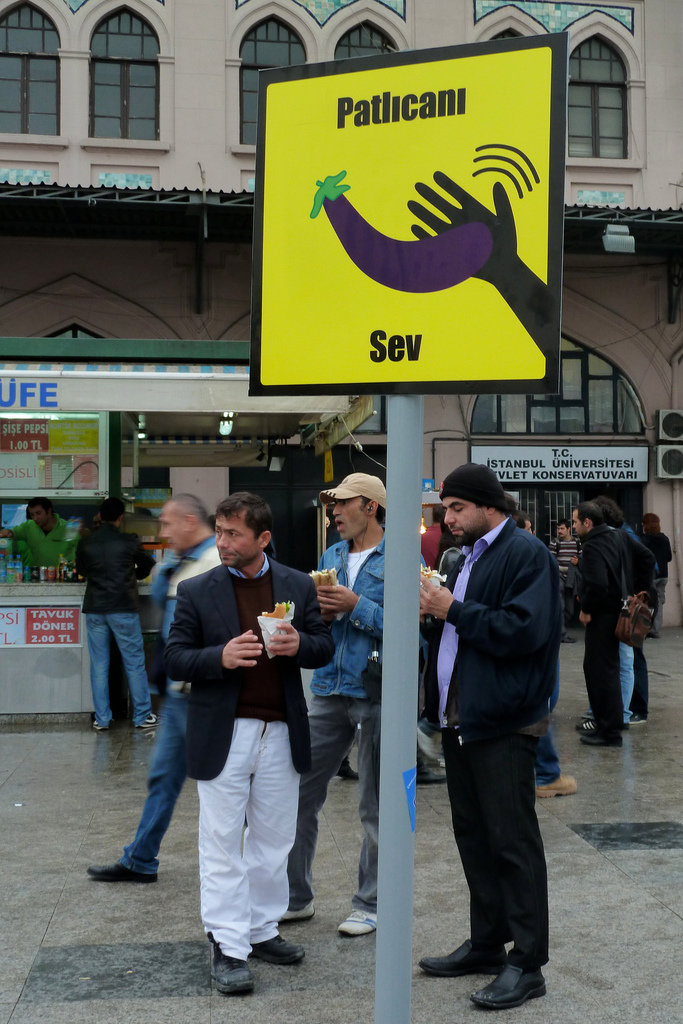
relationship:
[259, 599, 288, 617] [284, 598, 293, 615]
sandwich with lettuce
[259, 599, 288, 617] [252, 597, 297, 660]
sandwich wrapped in paper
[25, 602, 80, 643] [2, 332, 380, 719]
sign on kiosk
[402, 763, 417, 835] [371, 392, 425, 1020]
sign on utility pole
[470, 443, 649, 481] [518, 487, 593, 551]
sign above doorway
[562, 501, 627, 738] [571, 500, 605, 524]
man with hair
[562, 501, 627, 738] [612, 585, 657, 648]
man carries bag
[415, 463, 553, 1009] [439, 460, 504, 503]
man in beanie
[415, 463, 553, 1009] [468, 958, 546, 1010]
man wears shoe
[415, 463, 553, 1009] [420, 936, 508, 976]
man wears shoe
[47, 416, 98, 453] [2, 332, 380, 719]
sign in kiosk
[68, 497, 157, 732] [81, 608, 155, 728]
man in jeans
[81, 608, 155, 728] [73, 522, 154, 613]
jeans and jacket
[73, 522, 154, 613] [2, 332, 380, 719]
jacket at kiosk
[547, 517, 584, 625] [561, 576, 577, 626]
man in pants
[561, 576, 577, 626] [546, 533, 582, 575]
pants on top